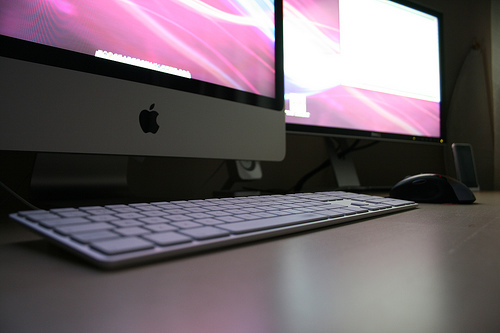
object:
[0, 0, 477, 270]
computer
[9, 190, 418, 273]
keyboard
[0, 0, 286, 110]
screen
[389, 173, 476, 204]
mouse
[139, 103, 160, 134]
apple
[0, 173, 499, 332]
desk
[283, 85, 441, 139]
purple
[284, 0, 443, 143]
screens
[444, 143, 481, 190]
speakers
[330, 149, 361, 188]
stands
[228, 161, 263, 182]
speaker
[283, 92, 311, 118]
words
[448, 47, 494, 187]
ironing board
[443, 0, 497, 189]
background